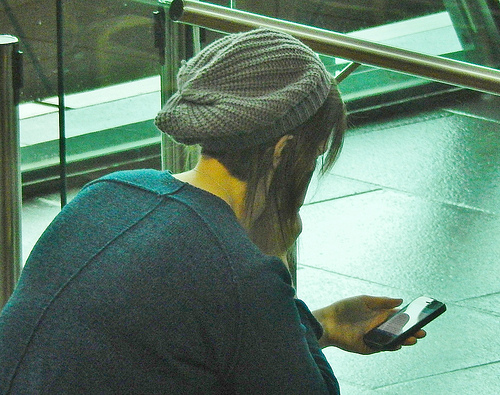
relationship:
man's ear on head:
[268, 134, 301, 180] [149, 14, 359, 222]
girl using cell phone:
[70, 14, 387, 382] [352, 294, 440, 357]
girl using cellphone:
[0, 26, 430, 394] [364, 292, 445, 357]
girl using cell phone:
[0, 26, 430, 394] [359, 290, 447, 350]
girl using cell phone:
[0, 26, 430, 394] [377, 269, 450, 348]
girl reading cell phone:
[0, 26, 430, 394] [358, 294, 446, 350]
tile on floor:
[22, 93, 499, 393] [20, 88, 497, 393]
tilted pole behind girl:
[168, 0, 498, 96] [0, 26, 430, 394]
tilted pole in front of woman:
[332, 62, 365, 89] [95, 34, 389, 354]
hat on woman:
[117, 46, 319, 167] [43, 28, 334, 387]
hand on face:
[245, 176, 300, 258] [289, 129, 326, 219]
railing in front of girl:
[170, 0, 499, 95] [0, 26, 430, 394]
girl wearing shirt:
[0, 26, 430, 394] [3, 167, 343, 391]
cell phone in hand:
[367, 294, 446, 350] [311, 294, 427, 357]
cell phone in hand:
[367, 294, 446, 350] [12, 24, 447, 394]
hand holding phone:
[326, 298, 426, 340] [329, 289, 417, 352]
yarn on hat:
[172, 52, 187, 73] [149, 0, 339, 160]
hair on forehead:
[213, 80, 346, 246] [317, 104, 339, 152]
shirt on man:
[3, 167, 343, 391] [109, 123, 258, 265]